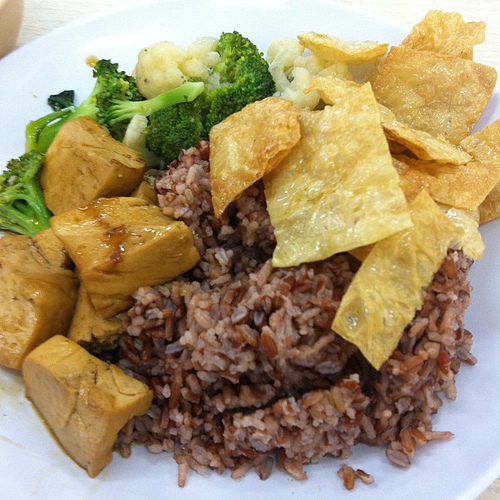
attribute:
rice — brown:
[335, 464, 375, 493]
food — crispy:
[208, 7, 498, 371]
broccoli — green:
[1, 30, 280, 234]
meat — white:
[7, 129, 168, 451]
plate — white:
[8, 19, 473, 498]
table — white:
[4, 2, 144, 86]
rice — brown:
[112, 231, 486, 493]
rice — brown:
[144, 279, 354, 471]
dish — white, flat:
[1, 1, 498, 498]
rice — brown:
[132, 240, 464, 470]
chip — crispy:
[207, 93, 302, 219]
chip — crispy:
[334, 186, 460, 368]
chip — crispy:
[268, 82, 418, 269]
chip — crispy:
[378, 117, 474, 167]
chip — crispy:
[374, 46, 499, 138]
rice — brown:
[88, 140, 478, 488]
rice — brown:
[130, 265, 446, 465]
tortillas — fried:
[38, 122, 423, 389]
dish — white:
[9, 14, 101, 81]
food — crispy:
[210, 88, 415, 262]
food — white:
[125, 49, 258, 114]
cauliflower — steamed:
[213, 29, 275, 98]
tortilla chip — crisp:
[331, 190, 456, 369]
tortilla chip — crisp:
[263, 82, 412, 267]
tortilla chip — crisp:
[298, 16, 388, 63]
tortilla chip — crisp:
[373, 35, 498, 145]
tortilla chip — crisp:
[395, 147, 496, 213]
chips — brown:
[207, 18, 499, 372]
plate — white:
[1, 0, 498, 498]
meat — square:
[39, 130, 175, 292]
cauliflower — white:
[141, 29, 224, 88]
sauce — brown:
[88, 198, 160, 273]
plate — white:
[9, 435, 496, 499]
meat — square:
[16, 331, 149, 481]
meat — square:
[0, 219, 79, 369]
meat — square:
[46, 190, 194, 347]